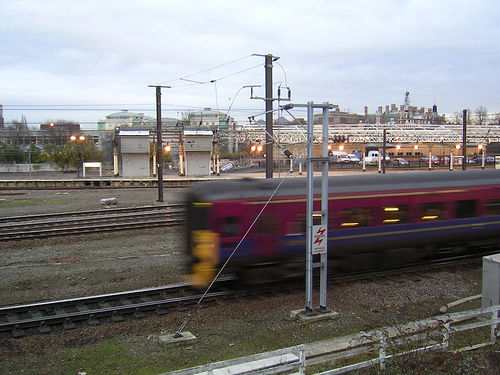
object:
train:
[175, 167, 499, 288]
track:
[3, 281, 228, 333]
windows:
[295, 197, 500, 227]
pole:
[288, 101, 342, 322]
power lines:
[4, 96, 499, 168]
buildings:
[4, 90, 499, 177]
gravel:
[3, 239, 181, 281]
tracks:
[3, 203, 197, 336]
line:
[177, 162, 302, 332]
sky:
[1, 1, 499, 123]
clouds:
[41, 8, 305, 104]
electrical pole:
[256, 48, 284, 177]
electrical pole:
[146, 78, 174, 204]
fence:
[254, 304, 500, 374]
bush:
[364, 282, 484, 371]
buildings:
[6, 88, 496, 160]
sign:
[311, 222, 328, 255]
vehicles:
[333, 148, 496, 171]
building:
[268, 121, 499, 166]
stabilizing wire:
[176, 143, 304, 334]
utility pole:
[290, 96, 337, 314]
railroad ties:
[3, 298, 238, 340]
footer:
[291, 301, 339, 325]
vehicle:
[365, 147, 387, 167]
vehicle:
[335, 151, 349, 166]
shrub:
[357, 282, 478, 373]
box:
[478, 251, 500, 320]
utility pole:
[249, 50, 284, 179]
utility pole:
[146, 82, 173, 203]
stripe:
[279, 216, 500, 260]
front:
[174, 178, 221, 290]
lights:
[337, 204, 439, 229]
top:
[193, 166, 499, 200]